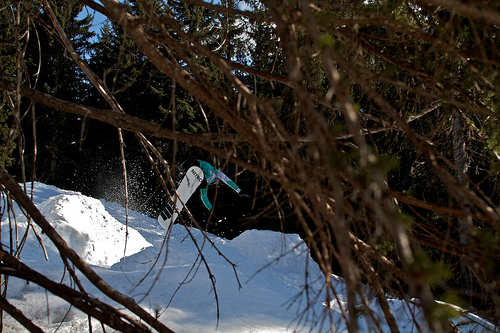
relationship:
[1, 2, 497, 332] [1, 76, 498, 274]
tree has branch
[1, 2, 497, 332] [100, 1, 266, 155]
tree has branch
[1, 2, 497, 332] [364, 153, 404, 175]
tree has leaf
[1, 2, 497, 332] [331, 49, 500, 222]
tree has branch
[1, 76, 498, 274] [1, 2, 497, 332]
branch on tree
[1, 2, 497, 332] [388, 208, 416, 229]
tree has leaf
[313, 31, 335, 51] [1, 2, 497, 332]
leaf on tree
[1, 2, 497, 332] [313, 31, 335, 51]
tree has leaf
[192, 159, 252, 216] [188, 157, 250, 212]
snowboarder in suit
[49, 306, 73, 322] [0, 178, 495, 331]
hole in snow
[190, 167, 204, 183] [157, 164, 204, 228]
logo on snowboard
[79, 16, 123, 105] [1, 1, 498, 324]
pine tree in forest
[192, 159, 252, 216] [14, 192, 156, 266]
snowboarder jumping jump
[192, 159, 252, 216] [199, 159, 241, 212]
snowboarder wearing jacket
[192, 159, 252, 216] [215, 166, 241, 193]
snowboarder has arm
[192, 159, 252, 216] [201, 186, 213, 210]
snowboarder has arm